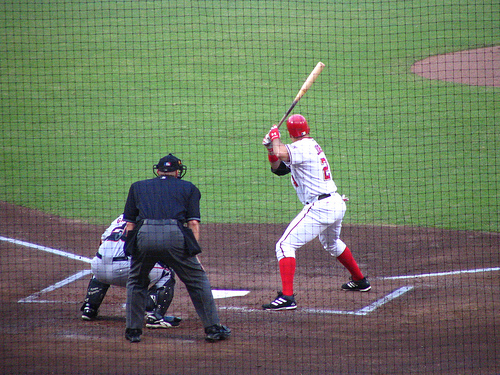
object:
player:
[261, 113, 372, 312]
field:
[0, 3, 499, 371]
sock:
[279, 257, 296, 296]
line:
[0, 230, 95, 269]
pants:
[275, 193, 348, 262]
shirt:
[284, 137, 337, 202]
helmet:
[287, 114, 310, 138]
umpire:
[121, 153, 232, 344]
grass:
[3, 3, 500, 230]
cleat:
[360, 286, 372, 292]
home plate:
[211, 289, 250, 301]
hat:
[158, 153, 182, 172]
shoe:
[261, 290, 299, 311]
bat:
[264, 61, 327, 144]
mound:
[407, 39, 498, 89]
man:
[80, 212, 183, 328]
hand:
[269, 124, 281, 140]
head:
[286, 114, 310, 142]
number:
[321, 157, 331, 179]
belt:
[318, 193, 332, 200]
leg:
[125, 251, 155, 327]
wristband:
[268, 154, 279, 163]